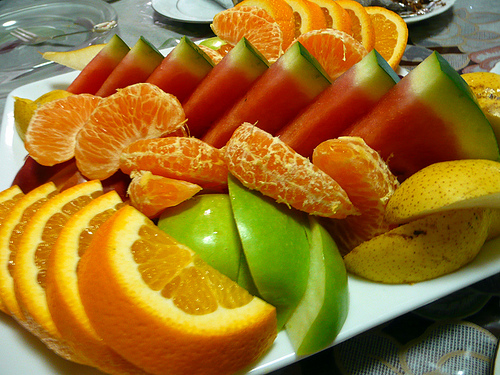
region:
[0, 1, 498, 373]
a white plate full of fresh fruit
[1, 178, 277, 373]
five slices of fresh orange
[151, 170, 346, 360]
four slices of a green apple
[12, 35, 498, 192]
seven slices of fresh watermelon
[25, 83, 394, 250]
six small slices of an orange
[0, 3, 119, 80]
a glass dinner plate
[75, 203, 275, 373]
one slice of a fresh orange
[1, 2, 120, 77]
a dinner fork sitting on a plate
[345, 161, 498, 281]
two slices of a golden delicious apples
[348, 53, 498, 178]
a slice of seedless watermelon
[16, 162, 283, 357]
orange slices on a fruit plate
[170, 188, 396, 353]
green apples on a white plate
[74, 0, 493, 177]
watermelon pieces in a row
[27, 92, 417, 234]
oranges peeled and juicy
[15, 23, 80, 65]
a glass plate with a fork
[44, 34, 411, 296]
a fruit plate of apples, oranges and watermelon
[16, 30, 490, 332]
the fruit is on a square plate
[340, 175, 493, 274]
some lemon wedges garnish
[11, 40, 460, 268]
the fruit comes in many flavors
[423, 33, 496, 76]
a pattern on the table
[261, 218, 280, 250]
the apple is green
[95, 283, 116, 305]
the peel is orange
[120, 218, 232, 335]
the orange is in slices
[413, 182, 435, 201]
the pear is yellow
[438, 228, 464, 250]
the pear has brown spots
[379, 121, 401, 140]
the melon is red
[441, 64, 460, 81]
the rine is green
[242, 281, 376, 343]
the fruit is on the plate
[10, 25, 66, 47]
the fork is silver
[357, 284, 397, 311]
the plate is white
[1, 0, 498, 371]
Plate of assorted fruits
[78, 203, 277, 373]
Slice of an orange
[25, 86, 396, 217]
Sections of a clementine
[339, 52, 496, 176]
Slice of a watermelon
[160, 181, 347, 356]
Cut up green apple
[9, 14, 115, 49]
Metal fork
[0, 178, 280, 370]
Five orange slices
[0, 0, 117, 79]
Clear plate with a fork on it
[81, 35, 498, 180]
Slices of watermelon and clementine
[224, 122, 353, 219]
Section of a clementine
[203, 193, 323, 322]
Green apples on the plate.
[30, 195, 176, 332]
Sliced oranges on the plate.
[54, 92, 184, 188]
Tangerines slices on top of gren apples.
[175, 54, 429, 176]
Slice watermelon on the dish.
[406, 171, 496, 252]
Yellow apple on the edge of plate.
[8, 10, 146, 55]
Fork on the plate.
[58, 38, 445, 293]
Fruits on the plate.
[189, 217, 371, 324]
The apples are green.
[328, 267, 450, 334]
The plate is white.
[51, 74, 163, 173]
Tangerines on the watermelon.